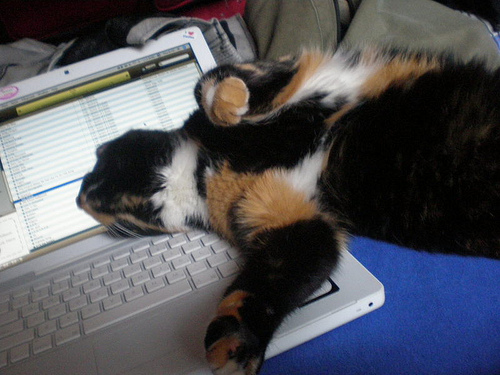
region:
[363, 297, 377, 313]
edge of a laptop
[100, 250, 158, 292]
key pad of a laptop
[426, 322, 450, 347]
top of a table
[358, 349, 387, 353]
part of a blue table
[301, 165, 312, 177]
white patch on a cat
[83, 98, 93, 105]
screen of a laptop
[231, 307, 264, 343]
paws of a cat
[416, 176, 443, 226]
back body of a cat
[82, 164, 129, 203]
face of a cat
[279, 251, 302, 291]
edge of a leg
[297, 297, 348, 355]
edge of a keyboard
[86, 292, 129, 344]
part of a button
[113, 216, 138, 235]
part of a whisker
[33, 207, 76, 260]
part of a screen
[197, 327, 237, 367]
edge of a paw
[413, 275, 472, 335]
part of a surface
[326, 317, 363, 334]
edge of a keyboard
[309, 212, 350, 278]
part of a knee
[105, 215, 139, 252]
part of a whisker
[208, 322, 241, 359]
edge of a paw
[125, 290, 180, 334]
part of a button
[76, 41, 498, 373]
Calico cat lying on computer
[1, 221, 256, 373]
keyboard of a laptop computer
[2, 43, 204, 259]
Laptop monitor screen with lots of data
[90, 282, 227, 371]
Laptop keyboard's trackpad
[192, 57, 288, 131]
Cat's paw in the air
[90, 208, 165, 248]
cat's whiskers on its face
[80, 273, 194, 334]
The spacebar of a keyboard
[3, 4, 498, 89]
Various clothing items behind computer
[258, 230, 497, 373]
Blue surface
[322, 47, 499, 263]
Cat's furry belly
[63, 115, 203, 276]
a cat resting it's head on a computer.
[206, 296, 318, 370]
a cats paw on a computer.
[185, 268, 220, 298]
a computer key.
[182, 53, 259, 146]
a paw of a cat on it's chest.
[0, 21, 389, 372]
an open laptop computer.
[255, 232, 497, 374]
a blue table surface.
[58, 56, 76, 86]
a camera lense on a computer.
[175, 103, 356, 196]
a chest on a cat.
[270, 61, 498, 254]
a hairy cat body.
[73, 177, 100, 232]
a cat's nose.